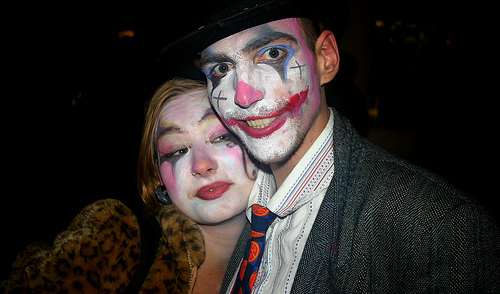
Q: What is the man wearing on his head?
A: A hat.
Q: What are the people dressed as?
A: Clowns.